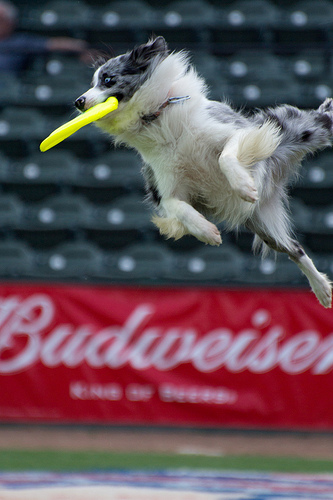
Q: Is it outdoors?
A: Yes, it is outdoors.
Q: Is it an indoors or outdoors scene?
A: It is outdoors.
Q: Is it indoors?
A: No, it is outdoors.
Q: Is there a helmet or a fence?
A: No, there are no fences or helmets.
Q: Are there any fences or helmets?
A: No, there are no fences or helmets.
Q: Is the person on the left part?
A: Yes, the person is on the left of the image.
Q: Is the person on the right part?
A: No, the person is on the left of the image.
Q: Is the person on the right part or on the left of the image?
A: The person is on the left of the image.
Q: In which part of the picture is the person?
A: The person is on the left of the image.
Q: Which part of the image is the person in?
A: The person is on the left of the image.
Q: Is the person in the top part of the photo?
A: Yes, the person is in the top of the image.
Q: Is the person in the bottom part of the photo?
A: No, the person is in the top of the image.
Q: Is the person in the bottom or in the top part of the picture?
A: The person is in the top of the image.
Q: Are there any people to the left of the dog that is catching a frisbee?
A: Yes, there is a person to the left of the dog.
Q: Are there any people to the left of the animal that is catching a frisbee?
A: Yes, there is a person to the left of the dog.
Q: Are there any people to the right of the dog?
A: No, the person is to the left of the dog.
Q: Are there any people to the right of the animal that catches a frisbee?
A: No, the person is to the left of the dog.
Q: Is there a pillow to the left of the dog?
A: No, there is a person to the left of the dog.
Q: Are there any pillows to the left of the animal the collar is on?
A: No, there is a person to the left of the dog.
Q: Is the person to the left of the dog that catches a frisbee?
A: Yes, the person is to the left of the dog.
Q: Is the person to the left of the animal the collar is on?
A: Yes, the person is to the left of the dog.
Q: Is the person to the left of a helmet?
A: No, the person is to the left of the dog.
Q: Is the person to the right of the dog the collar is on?
A: No, the person is to the left of the dog.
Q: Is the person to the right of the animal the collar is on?
A: No, the person is to the left of the dog.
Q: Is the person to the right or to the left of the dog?
A: The person is to the left of the dog.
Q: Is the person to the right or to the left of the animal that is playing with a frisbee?
A: The person is to the left of the dog.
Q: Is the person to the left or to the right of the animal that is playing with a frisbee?
A: The person is to the left of the dog.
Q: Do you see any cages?
A: No, there are no cages.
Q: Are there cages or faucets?
A: No, there are no cages or faucets.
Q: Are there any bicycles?
A: No, there are no bicycles.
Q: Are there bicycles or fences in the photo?
A: No, there are no bicycles or fences.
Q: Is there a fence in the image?
A: No, there are no fences.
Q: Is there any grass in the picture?
A: Yes, there is grass.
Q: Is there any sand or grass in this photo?
A: Yes, there is grass.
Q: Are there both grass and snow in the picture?
A: No, there is grass but no snow.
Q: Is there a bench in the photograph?
A: No, there are no benches.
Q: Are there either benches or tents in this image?
A: No, there are no benches or tents.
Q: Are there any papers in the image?
A: No, there are no papers.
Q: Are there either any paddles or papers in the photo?
A: No, there are no papers or paddles.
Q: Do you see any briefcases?
A: No, there are no briefcases.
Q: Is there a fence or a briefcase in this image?
A: No, there are no briefcases or fences.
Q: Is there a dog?
A: Yes, there is a dog.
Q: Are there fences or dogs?
A: Yes, there is a dog.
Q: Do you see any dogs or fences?
A: Yes, there is a dog.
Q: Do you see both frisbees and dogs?
A: Yes, there are both a dog and a frisbee.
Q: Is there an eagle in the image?
A: No, there are no eagles.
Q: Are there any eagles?
A: No, there are no eagles.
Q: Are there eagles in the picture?
A: No, there are no eagles.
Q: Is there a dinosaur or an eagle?
A: No, there are no eagles or dinosaurs.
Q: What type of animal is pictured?
A: The animal is a dog.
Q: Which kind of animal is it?
A: The animal is a dog.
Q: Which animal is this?
A: This is a dog.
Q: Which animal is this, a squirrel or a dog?
A: This is a dog.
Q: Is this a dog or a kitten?
A: This is a dog.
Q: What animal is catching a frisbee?
A: The dog is catching a frisbee.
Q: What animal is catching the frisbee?
A: The dog is catching a frisbee.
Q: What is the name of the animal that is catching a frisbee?
A: The animal is a dog.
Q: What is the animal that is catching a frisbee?
A: The animal is a dog.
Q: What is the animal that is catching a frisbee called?
A: The animal is a dog.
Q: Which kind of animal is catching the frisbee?
A: The animal is a dog.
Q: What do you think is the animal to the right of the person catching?
A: The dog is catching a frisbee.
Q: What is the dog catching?
A: The dog is catching a frisbee.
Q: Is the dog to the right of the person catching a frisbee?
A: Yes, the dog is catching a frisbee.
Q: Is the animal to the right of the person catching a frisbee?
A: Yes, the dog is catching a frisbee.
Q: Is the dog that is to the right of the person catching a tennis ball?
A: No, the dog is catching a frisbee.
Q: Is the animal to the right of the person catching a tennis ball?
A: No, the dog is catching a frisbee.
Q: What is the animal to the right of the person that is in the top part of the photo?
A: The animal is a dog.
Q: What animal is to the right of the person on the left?
A: The animal is a dog.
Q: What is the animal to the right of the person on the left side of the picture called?
A: The animal is a dog.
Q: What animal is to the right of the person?
A: The animal is a dog.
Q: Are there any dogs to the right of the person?
A: Yes, there is a dog to the right of the person.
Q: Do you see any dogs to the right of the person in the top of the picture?
A: Yes, there is a dog to the right of the person.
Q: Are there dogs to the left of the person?
A: No, the dog is to the right of the person.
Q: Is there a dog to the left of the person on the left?
A: No, the dog is to the right of the person.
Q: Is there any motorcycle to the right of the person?
A: No, there is a dog to the right of the person.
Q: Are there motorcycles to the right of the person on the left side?
A: No, there is a dog to the right of the person.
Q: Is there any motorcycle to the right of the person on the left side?
A: No, there is a dog to the right of the person.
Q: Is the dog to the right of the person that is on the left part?
A: Yes, the dog is to the right of the person.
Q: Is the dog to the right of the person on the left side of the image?
A: Yes, the dog is to the right of the person.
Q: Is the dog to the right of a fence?
A: No, the dog is to the right of the person.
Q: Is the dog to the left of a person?
A: No, the dog is to the right of a person.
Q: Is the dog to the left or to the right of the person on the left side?
A: The dog is to the right of the person.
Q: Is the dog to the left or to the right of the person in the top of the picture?
A: The dog is to the right of the person.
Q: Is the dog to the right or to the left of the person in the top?
A: The dog is to the right of the person.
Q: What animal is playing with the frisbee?
A: The dog is playing with the frisbee.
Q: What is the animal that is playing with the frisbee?
A: The animal is a dog.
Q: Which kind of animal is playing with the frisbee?
A: The animal is a dog.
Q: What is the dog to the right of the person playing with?
A: The dog is playing with a frisbee.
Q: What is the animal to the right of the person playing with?
A: The dog is playing with a frisbee.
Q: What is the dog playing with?
A: The dog is playing with a frisbee.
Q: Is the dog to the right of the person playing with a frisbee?
A: Yes, the dog is playing with a frisbee.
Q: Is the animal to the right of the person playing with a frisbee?
A: Yes, the dog is playing with a frisbee.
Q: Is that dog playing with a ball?
A: No, the dog is playing with a frisbee.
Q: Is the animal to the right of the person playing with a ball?
A: No, the dog is playing with a frisbee.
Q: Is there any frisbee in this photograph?
A: Yes, there is a frisbee.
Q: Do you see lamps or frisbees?
A: Yes, there is a frisbee.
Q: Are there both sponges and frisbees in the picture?
A: No, there is a frisbee but no sponges.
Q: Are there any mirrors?
A: No, there are no mirrors.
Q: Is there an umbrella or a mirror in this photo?
A: No, there are no mirrors or umbrellas.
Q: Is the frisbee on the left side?
A: Yes, the frisbee is on the left of the image.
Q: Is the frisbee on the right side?
A: No, the frisbee is on the left of the image.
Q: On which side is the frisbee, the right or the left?
A: The frisbee is on the left of the image.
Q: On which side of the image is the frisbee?
A: The frisbee is on the left of the image.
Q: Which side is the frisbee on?
A: The frisbee is on the left of the image.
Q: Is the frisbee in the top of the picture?
A: Yes, the frisbee is in the top of the image.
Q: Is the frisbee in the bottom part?
A: No, the frisbee is in the top of the image.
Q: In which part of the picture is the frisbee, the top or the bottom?
A: The frisbee is in the top of the image.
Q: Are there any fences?
A: No, there are no fences.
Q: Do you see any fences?
A: No, there are no fences.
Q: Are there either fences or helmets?
A: No, there are no fences or helmets.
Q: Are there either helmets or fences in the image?
A: No, there are no fences or helmets.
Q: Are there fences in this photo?
A: No, there are no fences.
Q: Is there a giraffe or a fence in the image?
A: No, there are no fences or giraffes.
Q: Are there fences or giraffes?
A: No, there are no fences or giraffes.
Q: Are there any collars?
A: Yes, there is a collar.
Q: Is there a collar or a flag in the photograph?
A: Yes, there is a collar.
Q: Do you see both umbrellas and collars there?
A: No, there is a collar but no umbrellas.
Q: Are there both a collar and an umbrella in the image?
A: No, there is a collar but no umbrellas.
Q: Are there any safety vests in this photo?
A: No, there are no safety vests.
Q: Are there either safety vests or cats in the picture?
A: No, there are no safety vests or cats.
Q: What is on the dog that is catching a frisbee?
A: The collar is on the dog.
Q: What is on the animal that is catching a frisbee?
A: The collar is on the dog.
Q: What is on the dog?
A: The collar is on the dog.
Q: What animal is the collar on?
A: The collar is on the dog.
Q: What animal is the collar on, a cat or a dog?
A: The collar is on a dog.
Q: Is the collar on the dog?
A: Yes, the collar is on the dog.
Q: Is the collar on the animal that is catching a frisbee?
A: Yes, the collar is on the dog.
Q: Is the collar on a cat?
A: No, the collar is on the dog.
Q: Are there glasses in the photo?
A: No, there are no glasses.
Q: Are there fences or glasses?
A: No, there are no glasses or fences.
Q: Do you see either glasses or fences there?
A: No, there are no glasses or fences.